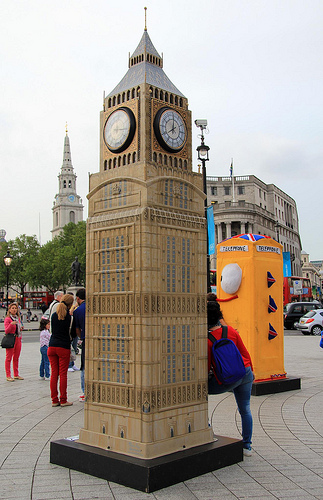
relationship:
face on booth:
[215, 260, 262, 313] [215, 231, 302, 399]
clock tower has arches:
[49, 3, 245, 495] [141, 171, 215, 227]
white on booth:
[215, 256, 240, 303] [239, 247, 282, 381]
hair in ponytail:
[60, 296, 69, 317] [58, 301, 68, 311]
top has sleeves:
[54, 321, 70, 344] [68, 318, 76, 350]